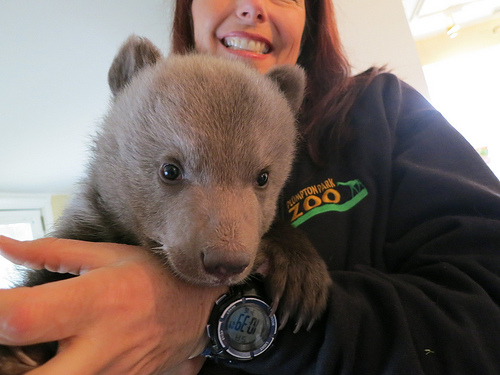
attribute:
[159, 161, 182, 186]
eye — black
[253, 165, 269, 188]
eye — black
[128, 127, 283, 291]
pupy — brown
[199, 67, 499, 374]
sweatshirt — black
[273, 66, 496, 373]
shirt — woman's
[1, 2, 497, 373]
lady — smiling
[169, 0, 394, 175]
hair — red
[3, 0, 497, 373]
person — lightskinned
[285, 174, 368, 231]
logo — zoo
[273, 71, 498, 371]
sweater — navy blue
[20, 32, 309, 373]
bear — baby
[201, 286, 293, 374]
watch — wrist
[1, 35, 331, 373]
bear — young, gray, baby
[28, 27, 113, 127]
ceiling — white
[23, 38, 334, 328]
puppy — looking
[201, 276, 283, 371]
wristwatch — black 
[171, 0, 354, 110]
head — woman's